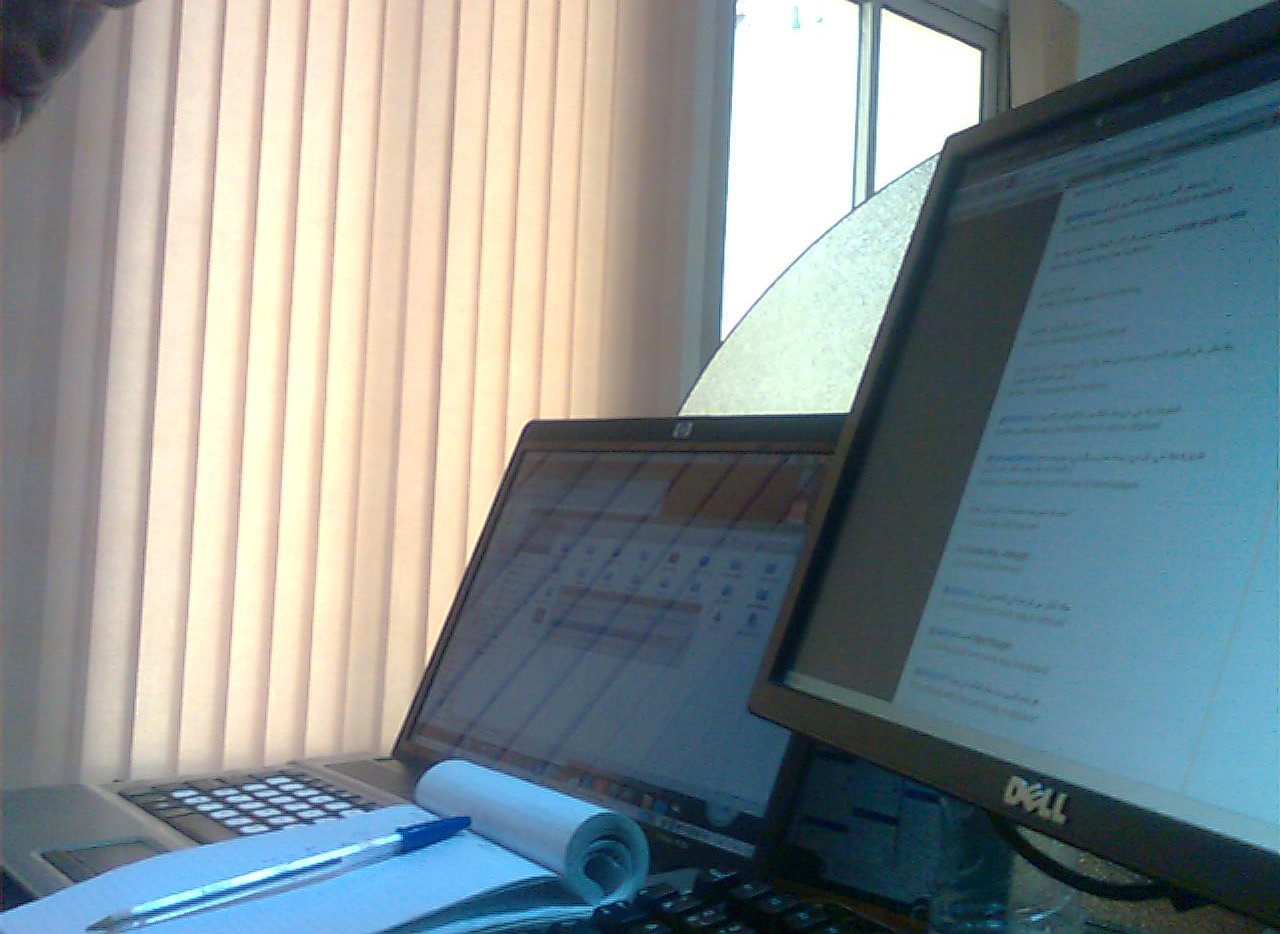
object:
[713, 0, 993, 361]
glass door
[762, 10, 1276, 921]
computer monitor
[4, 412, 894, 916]
hp laptop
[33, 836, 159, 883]
touchpad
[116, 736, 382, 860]
keyboard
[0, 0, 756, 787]
blinds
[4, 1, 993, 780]
sliding door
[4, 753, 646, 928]
notepad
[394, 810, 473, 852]
cap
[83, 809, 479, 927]
pen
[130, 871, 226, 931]
ink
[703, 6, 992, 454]
windows